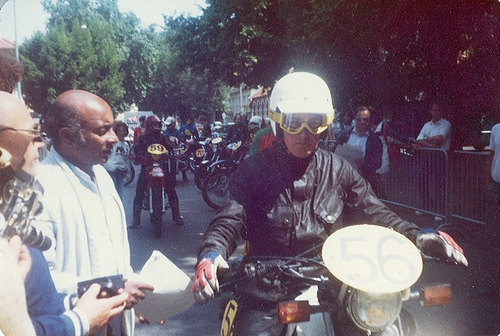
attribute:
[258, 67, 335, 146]
helmet — white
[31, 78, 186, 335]
man — bald, standing, balding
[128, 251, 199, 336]
paper — white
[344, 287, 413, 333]
light — off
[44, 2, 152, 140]
tree — green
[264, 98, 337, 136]
goggles — yellow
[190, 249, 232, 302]
glove — red, blue, white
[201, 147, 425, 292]
jacket — black, leather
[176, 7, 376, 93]
tree — green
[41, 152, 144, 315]
shirt — white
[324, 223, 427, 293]
circle — white, yellow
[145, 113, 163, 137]
helmet — dark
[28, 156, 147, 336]
jacket — light colored